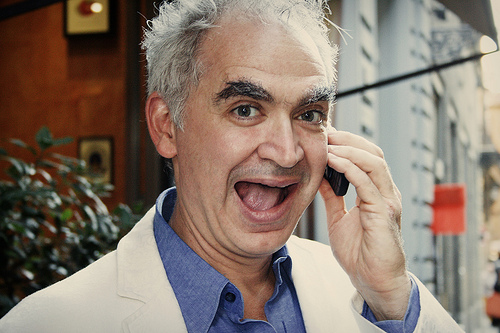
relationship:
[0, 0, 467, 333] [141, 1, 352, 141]
gentleman has hair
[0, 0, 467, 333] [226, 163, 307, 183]
gentleman has mustache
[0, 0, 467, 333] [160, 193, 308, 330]
gentleman wearing shirt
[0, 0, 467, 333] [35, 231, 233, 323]
gentleman wearing jacket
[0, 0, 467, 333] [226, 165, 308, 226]
gentleman has mouth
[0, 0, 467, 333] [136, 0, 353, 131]
gentleman with hair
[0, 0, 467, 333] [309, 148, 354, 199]
gentleman holding phone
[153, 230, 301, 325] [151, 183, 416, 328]
collar of a shirt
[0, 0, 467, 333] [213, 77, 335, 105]
gentleman has eyebrows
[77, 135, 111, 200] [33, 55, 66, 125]
art on a wall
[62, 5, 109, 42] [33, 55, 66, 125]
art on a wall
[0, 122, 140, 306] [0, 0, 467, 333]
plant behind gentleman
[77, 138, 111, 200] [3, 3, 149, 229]
art on wall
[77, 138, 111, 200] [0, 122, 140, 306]
art by plant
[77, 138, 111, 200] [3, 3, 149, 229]
art by wall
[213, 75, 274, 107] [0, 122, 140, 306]
eyebrow closest to plant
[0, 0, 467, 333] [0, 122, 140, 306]
gentleman closest to plant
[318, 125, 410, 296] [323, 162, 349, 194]
hand holding cellphone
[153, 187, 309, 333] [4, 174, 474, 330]
man's shirt under jacket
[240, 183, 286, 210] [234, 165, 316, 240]
tongue inside mouth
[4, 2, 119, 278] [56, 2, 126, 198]
panaling with pictures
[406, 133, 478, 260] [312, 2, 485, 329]
orange paper sticking out of building